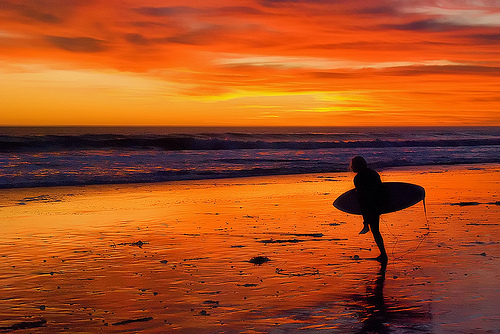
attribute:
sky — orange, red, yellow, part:
[1, 0, 499, 133]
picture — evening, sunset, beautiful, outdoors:
[1, 0, 499, 333]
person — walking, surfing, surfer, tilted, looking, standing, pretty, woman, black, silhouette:
[349, 153, 390, 262]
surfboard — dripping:
[332, 181, 425, 217]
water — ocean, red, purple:
[0, 123, 499, 187]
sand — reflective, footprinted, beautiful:
[0, 162, 500, 334]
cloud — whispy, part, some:
[213, 54, 463, 73]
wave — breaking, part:
[0, 131, 496, 151]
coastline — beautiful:
[0, 150, 499, 201]